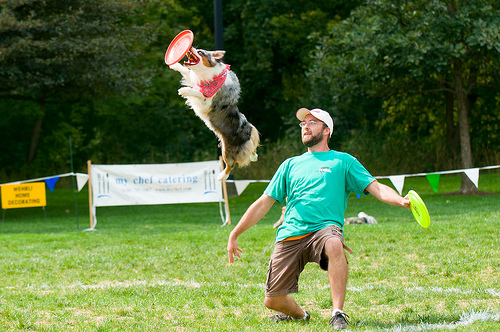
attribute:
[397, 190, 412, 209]
hand — green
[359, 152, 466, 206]
person — brown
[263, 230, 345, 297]
shorts — brown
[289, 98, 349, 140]
hat — white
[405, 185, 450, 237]
frisbee — yellow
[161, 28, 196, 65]
frisbee — red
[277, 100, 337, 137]
cap — white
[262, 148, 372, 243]
shirt — green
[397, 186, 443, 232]
frisbee — red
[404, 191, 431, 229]
frisbee — green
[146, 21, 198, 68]
frisbee — high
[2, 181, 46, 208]
sign — yellow, black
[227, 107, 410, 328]
man — green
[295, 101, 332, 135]
cap — white